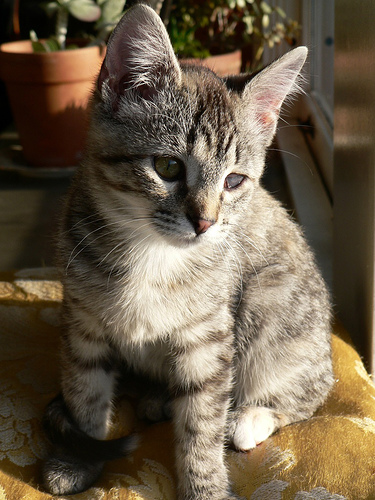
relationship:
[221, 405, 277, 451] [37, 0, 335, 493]
paw on cat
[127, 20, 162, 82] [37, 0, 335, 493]
furry ears on cat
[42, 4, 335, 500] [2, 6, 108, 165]
cat on flower pot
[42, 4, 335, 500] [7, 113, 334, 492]
cat sitting on table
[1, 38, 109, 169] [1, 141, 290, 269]
clay pot sitting on table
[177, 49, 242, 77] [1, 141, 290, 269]
clay pot sitting on table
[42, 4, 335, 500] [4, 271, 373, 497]
cat sitting on blanket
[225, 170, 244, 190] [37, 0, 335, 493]
eye socket on cat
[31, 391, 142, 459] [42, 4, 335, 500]
tail around cat